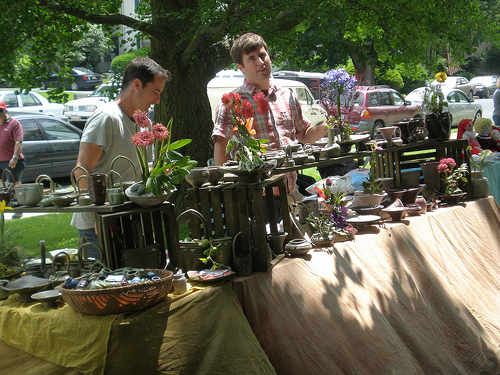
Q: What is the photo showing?
A: It is showing a parking lot.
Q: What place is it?
A: It is a parking lot.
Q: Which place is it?
A: It is a parking lot.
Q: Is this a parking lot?
A: Yes, it is a parking lot.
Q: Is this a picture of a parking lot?
A: Yes, it is showing a parking lot.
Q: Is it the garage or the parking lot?
A: It is the parking lot.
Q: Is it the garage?
A: No, it is the parking lot.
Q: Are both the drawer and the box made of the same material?
A: Yes, both the drawer and the box are made of wood.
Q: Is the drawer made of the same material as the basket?
A: Yes, both the drawer and the basket are made of wood.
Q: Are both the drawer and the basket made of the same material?
A: Yes, both the drawer and the basket are made of wood.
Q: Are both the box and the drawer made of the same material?
A: Yes, both the box and the drawer are made of wood.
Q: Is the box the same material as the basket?
A: Yes, both the box and the basket are made of wood.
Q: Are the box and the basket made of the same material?
A: Yes, both the box and the basket are made of wood.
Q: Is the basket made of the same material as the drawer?
A: Yes, both the basket and the drawer are made of wood.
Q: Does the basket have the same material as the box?
A: Yes, both the basket and the box are made of wood.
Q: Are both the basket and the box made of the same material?
A: Yes, both the basket and the box are made of wood.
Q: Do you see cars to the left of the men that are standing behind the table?
A: Yes, there is a car to the left of the men.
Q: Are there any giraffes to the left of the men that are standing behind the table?
A: No, there is a car to the left of the men.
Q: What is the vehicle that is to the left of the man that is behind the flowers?
A: The vehicle is a car.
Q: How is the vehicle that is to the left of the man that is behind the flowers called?
A: The vehicle is a car.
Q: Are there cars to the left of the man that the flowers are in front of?
A: Yes, there is a car to the left of the man.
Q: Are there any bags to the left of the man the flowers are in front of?
A: No, there is a car to the left of the man.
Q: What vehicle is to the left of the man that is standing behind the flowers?
A: The vehicle is a car.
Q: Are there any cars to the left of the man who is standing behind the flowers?
A: Yes, there is a car to the left of the man.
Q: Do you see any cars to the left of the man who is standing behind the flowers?
A: Yes, there is a car to the left of the man.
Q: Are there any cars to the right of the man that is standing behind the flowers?
A: No, the car is to the left of the man.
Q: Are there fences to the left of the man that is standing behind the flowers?
A: No, there is a car to the left of the man.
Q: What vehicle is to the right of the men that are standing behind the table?
A: The vehicle is a car.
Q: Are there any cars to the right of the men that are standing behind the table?
A: Yes, there is a car to the right of the men.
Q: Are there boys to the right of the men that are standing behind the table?
A: No, there is a car to the right of the men.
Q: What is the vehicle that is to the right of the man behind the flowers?
A: The vehicle is a car.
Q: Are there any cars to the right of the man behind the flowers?
A: Yes, there is a car to the right of the man.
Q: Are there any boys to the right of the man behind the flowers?
A: No, there is a car to the right of the man.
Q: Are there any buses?
A: No, there are no buses.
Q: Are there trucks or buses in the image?
A: No, there are no buses or trucks.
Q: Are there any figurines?
A: No, there are no figurines.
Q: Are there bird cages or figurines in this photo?
A: No, there are no figurines or bird cages.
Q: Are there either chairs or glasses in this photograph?
A: No, there are no glasses or chairs.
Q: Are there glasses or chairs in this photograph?
A: No, there are no glasses or chairs.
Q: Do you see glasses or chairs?
A: No, there are no glasses or chairs.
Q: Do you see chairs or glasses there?
A: No, there are no glasses or chairs.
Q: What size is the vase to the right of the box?
A: The vase is small.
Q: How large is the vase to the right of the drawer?
A: The vase is small.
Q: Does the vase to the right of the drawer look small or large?
A: The vase is small.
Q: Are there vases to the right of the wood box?
A: Yes, there is a vase to the right of the box.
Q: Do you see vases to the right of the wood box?
A: Yes, there is a vase to the right of the box.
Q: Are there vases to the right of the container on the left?
A: Yes, there is a vase to the right of the box.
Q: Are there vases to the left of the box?
A: No, the vase is to the right of the box.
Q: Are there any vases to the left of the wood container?
A: No, the vase is to the right of the box.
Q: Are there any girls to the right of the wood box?
A: No, there is a vase to the right of the box.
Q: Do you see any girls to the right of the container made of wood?
A: No, there is a vase to the right of the box.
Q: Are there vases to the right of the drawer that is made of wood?
A: Yes, there is a vase to the right of the drawer.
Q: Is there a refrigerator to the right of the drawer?
A: No, there is a vase to the right of the drawer.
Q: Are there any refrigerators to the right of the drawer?
A: No, there is a vase to the right of the drawer.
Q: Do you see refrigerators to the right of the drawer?
A: No, there is a vase to the right of the drawer.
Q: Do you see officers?
A: No, there are no officers.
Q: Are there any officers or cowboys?
A: No, there are no officers or cowboys.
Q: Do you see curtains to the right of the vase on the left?
A: No, there are men to the right of the vase.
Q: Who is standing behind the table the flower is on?
A: The men are standing behind the table.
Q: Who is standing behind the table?
A: The men are standing behind the table.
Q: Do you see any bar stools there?
A: No, there are no bar stools.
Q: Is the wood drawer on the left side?
A: Yes, the drawer is on the left of the image.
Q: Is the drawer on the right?
A: No, the drawer is on the left of the image.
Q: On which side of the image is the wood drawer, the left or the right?
A: The drawer is on the left of the image.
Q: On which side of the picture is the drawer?
A: The drawer is on the left of the image.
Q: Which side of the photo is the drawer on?
A: The drawer is on the left of the image.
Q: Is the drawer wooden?
A: Yes, the drawer is wooden.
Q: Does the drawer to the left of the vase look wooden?
A: Yes, the drawer is wooden.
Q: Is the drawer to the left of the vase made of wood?
A: Yes, the drawer is made of wood.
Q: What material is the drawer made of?
A: The drawer is made of wood.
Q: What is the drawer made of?
A: The drawer is made of wood.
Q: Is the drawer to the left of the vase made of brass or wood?
A: The drawer is made of wood.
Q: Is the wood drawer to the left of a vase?
A: Yes, the drawer is to the left of a vase.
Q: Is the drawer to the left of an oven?
A: No, the drawer is to the left of a vase.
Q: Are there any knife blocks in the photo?
A: No, there are no knife blocks.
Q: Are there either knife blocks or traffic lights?
A: No, there are no knife blocks or traffic lights.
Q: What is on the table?
A: The flower is on the table.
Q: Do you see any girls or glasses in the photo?
A: No, there are no glasses or girls.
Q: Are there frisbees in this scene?
A: No, there are no frisbees.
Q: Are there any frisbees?
A: No, there are no frisbees.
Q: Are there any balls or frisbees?
A: No, there are no frisbees or balls.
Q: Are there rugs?
A: No, there are no rugs.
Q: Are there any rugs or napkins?
A: No, there are no rugs or napkins.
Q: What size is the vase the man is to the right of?
A: The vase is small.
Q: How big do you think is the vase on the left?
A: The vase is small.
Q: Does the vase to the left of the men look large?
A: No, the vase is small.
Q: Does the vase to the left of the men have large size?
A: No, the vase is small.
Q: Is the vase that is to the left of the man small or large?
A: The vase is small.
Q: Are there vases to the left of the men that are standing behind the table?
A: Yes, there is a vase to the left of the men.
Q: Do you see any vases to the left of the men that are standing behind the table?
A: Yes, there is a vase to the left of the men.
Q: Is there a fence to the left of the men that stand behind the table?
A: No, there is a vase to the left of the men.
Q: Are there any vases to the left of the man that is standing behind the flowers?
A: Yes, there is a vase to the left of the man.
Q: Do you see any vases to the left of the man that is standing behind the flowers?
A: Yes, there is a vase to the left of the man.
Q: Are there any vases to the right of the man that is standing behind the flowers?
A: No, the vase is to the left of the man.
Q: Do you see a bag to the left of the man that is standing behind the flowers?
A: No, there is a vase to the left of the man.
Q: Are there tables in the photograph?
A: Yes, there is a table.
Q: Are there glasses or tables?
A: Yes, there is a table.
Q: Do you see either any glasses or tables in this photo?
A: Yes, there is a table.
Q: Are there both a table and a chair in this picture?
A: No, there is a table but no chairs.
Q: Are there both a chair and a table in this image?
A: No, there is a table but no chairs.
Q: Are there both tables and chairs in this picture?
A: No, there is a table but no chairs.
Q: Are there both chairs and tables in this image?
A: No, there is a table but no chairs.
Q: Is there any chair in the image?
A: No, there are no chairs.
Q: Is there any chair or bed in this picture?
A: No, there are no chairs or beds.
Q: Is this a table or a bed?
A: This is a table.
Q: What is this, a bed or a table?
A: This is a table.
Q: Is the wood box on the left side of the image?
A: Yes, the box is on the left of the image.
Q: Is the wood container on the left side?
A: Yes, the box is on the left of the image.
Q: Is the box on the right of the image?
A: No, the box is on the left of the image.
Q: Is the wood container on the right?
A: No, the box is on the left of the image.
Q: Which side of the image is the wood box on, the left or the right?
A: The box is on the left of the image.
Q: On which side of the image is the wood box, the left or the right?
A: The box is on the left of the image.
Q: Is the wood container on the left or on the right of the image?
A: The box is on the left of the image.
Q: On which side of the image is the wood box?
A: The box is on the left of the image.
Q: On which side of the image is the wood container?
A: The box is on the left of the image.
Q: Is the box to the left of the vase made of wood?
A: Yes, the box is made of wood.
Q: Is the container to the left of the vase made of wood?
A: Yes, the box is made of wood.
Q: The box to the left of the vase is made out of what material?
A: The box is made of wood.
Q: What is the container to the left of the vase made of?
A: The box is made of wood.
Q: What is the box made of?
A: The box is made of wood.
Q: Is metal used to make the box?
A: No, the box is made of wood.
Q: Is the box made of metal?
A: No, the box is made of wood.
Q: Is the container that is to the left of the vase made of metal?
A: No, the box is made of wood.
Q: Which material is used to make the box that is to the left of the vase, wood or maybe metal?
A: The box is made of wood.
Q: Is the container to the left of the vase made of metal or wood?
A: The box is made of wood.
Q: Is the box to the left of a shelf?
A: No, the box is to the left of the vase.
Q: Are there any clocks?
A: No, there are no clocks.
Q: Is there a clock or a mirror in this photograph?
A: No, there are no clocks or mirrors.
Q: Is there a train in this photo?
A: No, there are no trains.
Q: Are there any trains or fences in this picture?
A: No, there are no trains or fences.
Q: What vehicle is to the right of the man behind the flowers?
A: The vehicle is a car.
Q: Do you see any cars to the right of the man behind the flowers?
A: Yes, there is a car to the right of the man.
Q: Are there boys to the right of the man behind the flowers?
A: No, there is a car to the right of the man.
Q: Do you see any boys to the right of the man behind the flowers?
A: No, there is a car to the right of the man.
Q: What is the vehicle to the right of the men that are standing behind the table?
A: The vehicle is a car.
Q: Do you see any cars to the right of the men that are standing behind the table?
A: Yes, there is a car to the right of the men.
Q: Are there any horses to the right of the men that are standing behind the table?
A: No, there is a car to the right of the men.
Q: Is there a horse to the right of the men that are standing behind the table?
A: No, there is a car to the right of the men.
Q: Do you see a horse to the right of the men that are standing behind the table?
A: No, there is a car to the right of the men.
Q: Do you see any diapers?
A: No, there are no diapers.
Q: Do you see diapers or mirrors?
A: No, there are no diapers or mirrors.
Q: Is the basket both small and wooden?
A: Yes, the basket is small and wooden.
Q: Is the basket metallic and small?
A: No, the basket is small but wooden.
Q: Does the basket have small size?
A: Yes, the basket is small.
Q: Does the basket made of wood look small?
A: Yes, the basket is small.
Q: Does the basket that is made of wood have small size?
A: Yes, the basket is small.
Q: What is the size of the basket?
A: The basket is small.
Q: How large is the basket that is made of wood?
A: The basket is small.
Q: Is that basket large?
A: No, the basket is small.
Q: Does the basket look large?
A: No, the basket is small.